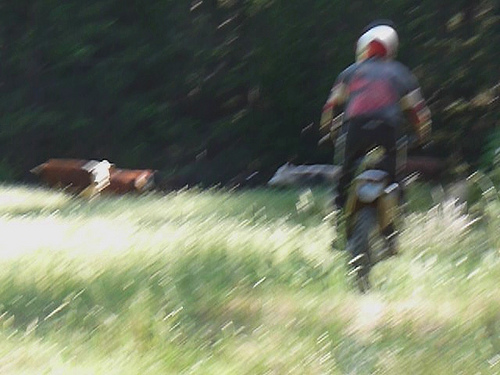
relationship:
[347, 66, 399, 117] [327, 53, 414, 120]
design on shirt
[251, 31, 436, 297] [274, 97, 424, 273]
person on bike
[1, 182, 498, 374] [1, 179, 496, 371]
grass on field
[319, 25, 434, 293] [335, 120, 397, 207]
person on pants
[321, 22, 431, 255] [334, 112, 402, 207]
boy on jeans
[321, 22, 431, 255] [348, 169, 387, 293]
boy on bike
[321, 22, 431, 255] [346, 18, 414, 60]
boy on helmet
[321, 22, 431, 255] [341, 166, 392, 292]
boy on bike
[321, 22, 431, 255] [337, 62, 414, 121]
boy on gray shirt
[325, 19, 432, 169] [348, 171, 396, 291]
boy on bike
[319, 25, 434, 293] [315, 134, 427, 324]
person standing on bike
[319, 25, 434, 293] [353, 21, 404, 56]
person wears a helmet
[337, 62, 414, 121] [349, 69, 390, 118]
gray shirt has a number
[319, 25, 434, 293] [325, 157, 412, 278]
person standing on motorcycle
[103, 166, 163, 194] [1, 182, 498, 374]
cow in grass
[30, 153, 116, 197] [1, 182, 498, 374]
cow in grass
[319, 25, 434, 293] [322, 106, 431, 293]
person on bike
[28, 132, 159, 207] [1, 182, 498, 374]
object at end of grass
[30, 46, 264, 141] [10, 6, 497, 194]
wall of trees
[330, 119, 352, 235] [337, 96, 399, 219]
leg in jeans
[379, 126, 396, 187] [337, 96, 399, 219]
leg in jeans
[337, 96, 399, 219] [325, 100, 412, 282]
jeans over bike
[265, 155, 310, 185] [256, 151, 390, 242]
head on animal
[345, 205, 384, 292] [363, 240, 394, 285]
tire with prongs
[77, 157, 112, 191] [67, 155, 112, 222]
head on cow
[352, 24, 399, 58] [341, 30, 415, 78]
helmet on head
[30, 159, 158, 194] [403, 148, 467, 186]
red truck on roadway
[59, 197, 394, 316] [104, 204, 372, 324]
field with grasses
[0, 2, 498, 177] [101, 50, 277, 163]
trees in background